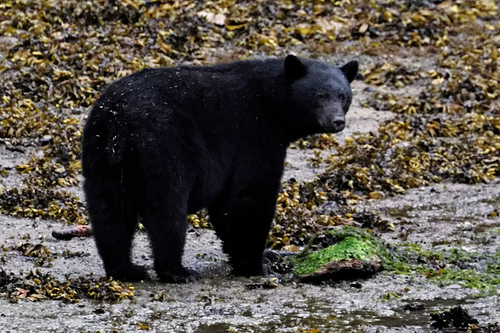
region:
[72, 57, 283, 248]
The bear is black.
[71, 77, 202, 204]
The bear is black.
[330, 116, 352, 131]
snout on the bear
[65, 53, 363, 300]
a large black bear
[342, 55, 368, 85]
an ear on the bear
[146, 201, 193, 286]
one of the hind legs on bear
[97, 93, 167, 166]
the back side of bear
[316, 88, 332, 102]
one of the bear's eyes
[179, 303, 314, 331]
part of land that bear is standing on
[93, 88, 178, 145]
debris on back of bear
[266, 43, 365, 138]
the head on the bear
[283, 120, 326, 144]
the neck on the bear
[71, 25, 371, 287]
An all black bear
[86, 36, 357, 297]
The bear is standing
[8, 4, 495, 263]
Yellow and brown leaves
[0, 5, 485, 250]
The yellow and brown leaves are on the ground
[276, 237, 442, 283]
Green moss on a rock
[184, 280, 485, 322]
Puddles of brown water on the ground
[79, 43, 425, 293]
The bear's head is turned towards the camera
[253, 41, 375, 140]
The bear's ears are perked forward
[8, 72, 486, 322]
The ground is wet dirt and leaves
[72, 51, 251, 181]
The bear has dirt on its back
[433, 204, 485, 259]
part of a ground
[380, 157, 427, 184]
part of some dry leaves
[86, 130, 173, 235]
back of a bear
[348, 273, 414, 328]
part of a ground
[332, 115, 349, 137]
nose of a bear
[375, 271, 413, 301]
part of a ground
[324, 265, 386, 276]
edge of a rock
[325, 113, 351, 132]
Bear has black nose.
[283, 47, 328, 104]
Bear has black ear.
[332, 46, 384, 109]
Bear has black ear.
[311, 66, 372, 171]
Bear has black face.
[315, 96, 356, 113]
Bear has dark eyes.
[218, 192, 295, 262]
Bear has dark leg.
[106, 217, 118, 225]
Bear has dark leg.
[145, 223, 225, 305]
Bear has dark leg.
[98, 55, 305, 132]
Bear has black back.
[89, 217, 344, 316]
Bear is standing in dirt and leaves.